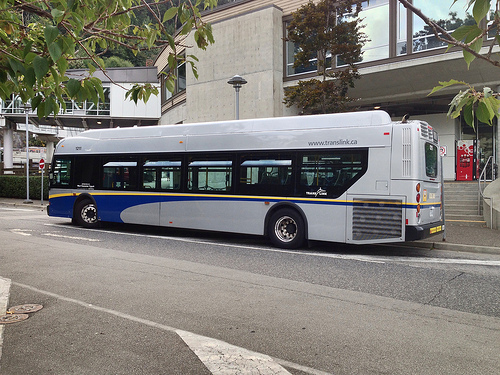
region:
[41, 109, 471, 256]
a bus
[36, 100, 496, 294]
a white and blue bus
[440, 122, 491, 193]
a red vending machine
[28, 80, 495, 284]
the bus has a yellow stripe on it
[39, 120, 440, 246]
the bus is run by translink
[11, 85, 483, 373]
a bus on a city street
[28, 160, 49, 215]
a stop sign on the corner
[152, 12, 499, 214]
a building beside the road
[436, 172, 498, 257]
stairs in front of a building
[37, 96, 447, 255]
a bus with a white roof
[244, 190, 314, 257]
tire is black and round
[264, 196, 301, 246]
tire is black and round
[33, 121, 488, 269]
white and blue city bus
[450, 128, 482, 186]
red and white drink machine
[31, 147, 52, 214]
red and white do not enter wrong way sign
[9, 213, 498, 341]
asphalt city street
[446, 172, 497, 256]
cement steps with metal handrail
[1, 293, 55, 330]
two man hole covers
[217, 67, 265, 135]
city street light on metal pole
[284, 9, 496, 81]
upper floor windows in building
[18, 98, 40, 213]
city street light on metal pole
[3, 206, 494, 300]
white lines painted on street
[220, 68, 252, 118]
a white lamp post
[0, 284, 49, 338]
a man whole cover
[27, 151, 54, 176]
a red street sign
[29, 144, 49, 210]
a sign on a metal post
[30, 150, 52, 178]
a do not enter sign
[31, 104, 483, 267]
a blue and white bus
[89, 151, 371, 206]
a row of windows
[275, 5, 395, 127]
a tall tree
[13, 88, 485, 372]
a not busy street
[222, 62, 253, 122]
a street lamp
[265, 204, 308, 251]
the rear wheel of a bus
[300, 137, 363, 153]
a website address at www.translink.ca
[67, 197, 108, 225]
the front wheel of a bus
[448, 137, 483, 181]
a soda vending machine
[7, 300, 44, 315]
a manhole cover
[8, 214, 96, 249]
a traffic arrow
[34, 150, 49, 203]
a do not enter sign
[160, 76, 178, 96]
a leaf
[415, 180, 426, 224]
the buses' left signal lights